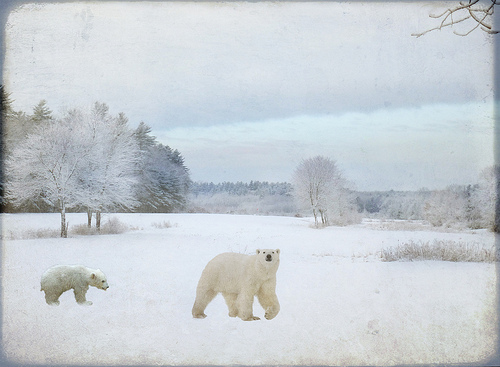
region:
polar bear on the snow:
[181, 242, 293, 324]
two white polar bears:
[38, 228, 300, 337]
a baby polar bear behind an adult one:
[28, 238, 310, 338]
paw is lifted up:
[258, 301, 280, 321]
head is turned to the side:
[251, 241, 286, 266]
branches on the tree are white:
[285, 155, 345, 230]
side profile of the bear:
[36, 259, 113, 311]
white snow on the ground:
[1, 205, 498, 364]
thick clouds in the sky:
[6, 8, 498, 195]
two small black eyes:
[262, 250, 279, 255]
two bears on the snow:
[32, 222, 315, 332]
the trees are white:
[2, 101, 142, 234]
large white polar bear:
[192, 244, 288, 323]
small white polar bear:
[42, 259, 113, 309]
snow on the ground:
[120, 323, 195, 363]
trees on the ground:
[1, 105, 145, 241]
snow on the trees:
[49, 120, 92, 153]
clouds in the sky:
[43, 5, 353, 85]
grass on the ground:
[417, 244, 481, 261]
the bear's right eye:
[256, 248, 267, 256]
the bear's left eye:
[271, 248, 278, 258]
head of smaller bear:
[91, 270, 116, 294]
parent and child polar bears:
[5, 99, 332, 354]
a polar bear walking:
[182, 132, 317, 346]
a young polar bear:
[20, 254, 137, 322]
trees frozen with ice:
[2, 101, 199, 248]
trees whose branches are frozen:
[1, 92, 373, 239]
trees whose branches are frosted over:
[0, 94, 375, 239]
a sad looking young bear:
[27, 252, 135, 324]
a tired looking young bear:
[18, 248, 144, 325]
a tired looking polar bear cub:
[25, 254, 150, 325]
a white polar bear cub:
[23, 256, 125, 323]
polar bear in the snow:
[178, 239, 303, 340]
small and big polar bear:
[28, 235, 307, 340]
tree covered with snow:
[13, 90, 142, 242]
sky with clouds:
[223, 18, 413, 142]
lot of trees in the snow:
[273, 177, 496, 229]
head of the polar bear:
[256, 246, 283, 265]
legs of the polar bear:
[233, 291, 276, 321]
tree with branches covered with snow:
[49, 129, 121, 190]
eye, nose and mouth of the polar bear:
[98, 275, 113, 290]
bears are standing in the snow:
[38, 245, 315, 346]